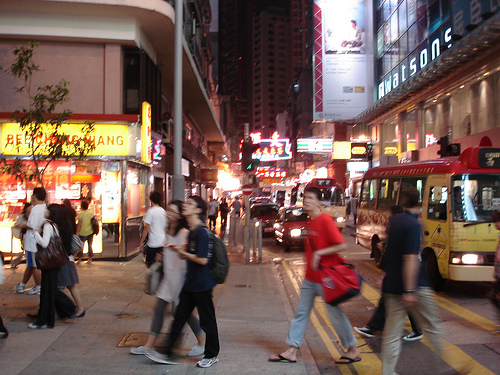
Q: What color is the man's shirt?
A: Red.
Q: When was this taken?
A: At Night.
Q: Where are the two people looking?
A: Up.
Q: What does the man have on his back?
A: A Backpack.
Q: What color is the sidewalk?
A: Gray.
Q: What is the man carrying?
A: A Duffle Bag.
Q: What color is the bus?
A: Red and Yellow.